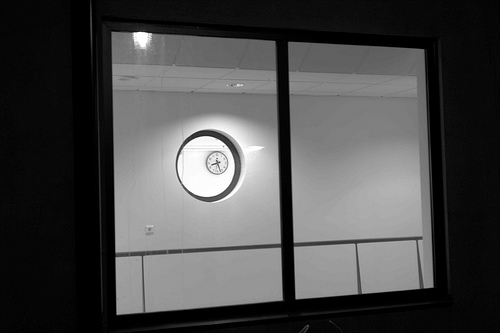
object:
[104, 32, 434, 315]
double window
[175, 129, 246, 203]
clock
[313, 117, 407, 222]
wall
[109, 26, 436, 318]
window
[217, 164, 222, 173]
hands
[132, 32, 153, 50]
light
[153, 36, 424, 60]
ceiling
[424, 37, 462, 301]
side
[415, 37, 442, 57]
window seal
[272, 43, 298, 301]
middle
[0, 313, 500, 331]
bottom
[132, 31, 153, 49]
glare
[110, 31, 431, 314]
window pane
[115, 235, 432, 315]
railing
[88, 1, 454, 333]
frame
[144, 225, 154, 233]
light switch